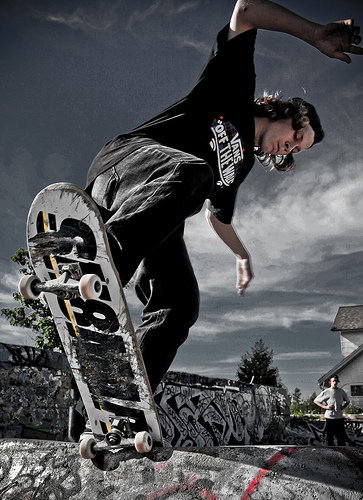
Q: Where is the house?
A: Behind the boy in the grey shirt.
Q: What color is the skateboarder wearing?
A: Black.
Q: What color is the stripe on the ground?
A: Red.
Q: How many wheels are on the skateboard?
A: Four.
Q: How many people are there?
A: Two.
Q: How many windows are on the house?
A: One.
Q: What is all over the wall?
A: Graffiti.